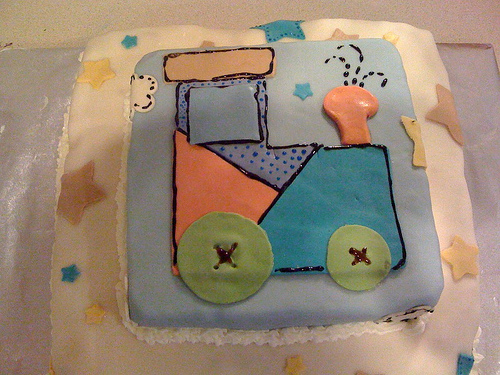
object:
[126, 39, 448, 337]
decoration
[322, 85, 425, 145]
stack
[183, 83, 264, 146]
window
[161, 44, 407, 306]
train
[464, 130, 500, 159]
ground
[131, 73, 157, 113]
cloud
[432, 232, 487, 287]
star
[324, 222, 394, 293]
wheel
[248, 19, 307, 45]
star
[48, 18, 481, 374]
cake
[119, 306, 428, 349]
icing border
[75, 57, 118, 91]
star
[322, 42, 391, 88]
smoke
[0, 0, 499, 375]
table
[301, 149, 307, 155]
dots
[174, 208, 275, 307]
wheel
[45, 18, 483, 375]
icing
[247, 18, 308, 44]
sparkles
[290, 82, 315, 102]
star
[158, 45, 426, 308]
drawing